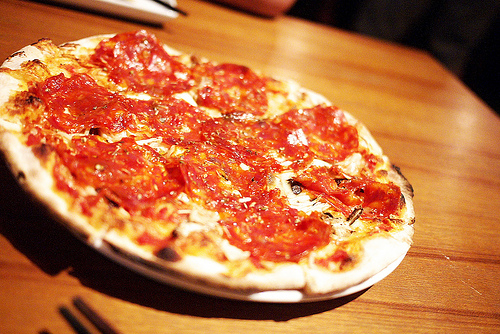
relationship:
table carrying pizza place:
[7, 26, 423, 304] [56, 40, 483, 309]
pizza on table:
[7, 26, 423, 304] [360, 79, 475, 288]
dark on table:
[436, 248, 488, 267] [285, 56, 460, 306]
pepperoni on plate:
[138, 116, 308, 191] [313, 255, 404, 294]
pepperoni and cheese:
[138, 116, 308, 191] [250, 189, 332, 231]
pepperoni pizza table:
[138, 116, 308, 191] [7, 26, 423, 304]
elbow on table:
[228, 0, 303, 23] [7, 26, 423, 304]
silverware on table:
[35, 290, 126, 333] [6, 37, 451, 327]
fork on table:
[35, 290, 126, 333] [6, 37, 451, 327]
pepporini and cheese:
[195, 119, 274, 163] [250, 189, 332, 231]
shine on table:
[385, 55, 453, 119] [6, 37, 451, 327]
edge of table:
[302, 33, 460, 72] [6, 37, 451, 327]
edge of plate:
[343, 272, 405, 293] [313, 255, 404, 294]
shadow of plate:
[0, 208, 55, 285] [313, 255, 404, 294]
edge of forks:
[54, 287, 89, 316] [35, 290, 126, 333]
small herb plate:
[186, 159, 267, 195] [313, 255, 404, 294]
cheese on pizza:
[250, 189, 332, 231] [7, 26, 423, 304]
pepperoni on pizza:
[138, 116, 308, 191] [7, 26, 423, 304]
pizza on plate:
[7, 26, 423, 304] [313, 255, 404, 294]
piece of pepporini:
[271, 113, 356, 158] [195, 119, 274, 163]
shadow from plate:
[0, 208, 55, 285] [313, 255, 404, 294]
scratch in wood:
[428, 255, 484, 305] [418, 112, 486, 298]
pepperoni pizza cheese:
[138, 116, 308, 191] [250, 189, 332, 231]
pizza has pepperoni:
[7, 26, 423, 304] [138, 116, 308, 191]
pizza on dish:
[7, 26, 423, 304] [198, 287, 301, 316]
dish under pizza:
[198, 287, 301, 316] [7, 26, 423, 304]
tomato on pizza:
[323, 250, 353, 263] [7, 26, 423, 304]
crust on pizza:
[315, 238, 410, 285] [7, 26, 423, 304]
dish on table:
[198, 287, 301, 316] [6, 37, 451, 327]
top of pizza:
[51, 42, 358, 253] [7, 26, 423, 304]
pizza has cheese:
[7, 26, 423, 304] [250, 189, 332, 231]